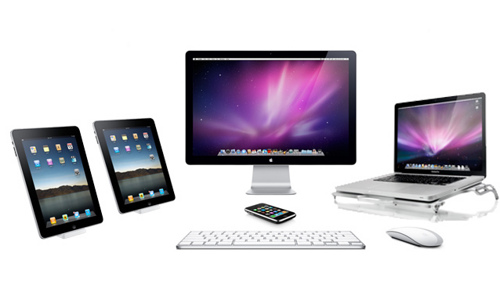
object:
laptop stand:
[332, 184, 497, 224]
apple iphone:
[243, 201, 297, 225]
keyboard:
[176, 228, 365, 253]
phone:
[239, 200, 299, 222]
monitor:
[174, 40, 365, 173]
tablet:
[1, 116, 103, 252]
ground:
[342, 147, 391, 217]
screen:
[189, 57, 354, 162]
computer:
[183, 47, 360, 196]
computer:
[333, 92, 493, 213]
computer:
[91, 117, 175, 214]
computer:
[0, 119, 106, 246]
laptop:
[332, 90, 499, 222]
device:
[176, 225, 366, 253]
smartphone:
[243, 199, 300, 225]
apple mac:
[332, 92, 487, 221]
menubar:
[392, 91, 487, 109]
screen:
[184, 55, 356, 168]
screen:
[392, 94, 485, 174]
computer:
[182, 44, 360, 211]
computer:
[338, 86, 498, 206]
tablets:
[3, 91, 180, 250]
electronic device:
[332, 91, 487, 204]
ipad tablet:
[93, 119, 180, 213]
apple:
[1, 117, 105, 236]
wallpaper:
[396, 97, 483, 172]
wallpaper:
[188, 53, 348, 158]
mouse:
[385, 226, 445, 247]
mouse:
[375, 220, 448, 254]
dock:
[350, 148, 487, 239]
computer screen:
[395, 105, 487, 175]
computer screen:
[191, 54, 346, 159]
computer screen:
[98, 125, 170, 201]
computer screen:
[15, 133, 95, 230]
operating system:
[244, 201, 296, 223]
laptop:
[333, 86, 499, 209]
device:
[10, 126, 102, 238]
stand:
[353, 164, 485, 235]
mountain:
[37, 177, 80, 195]